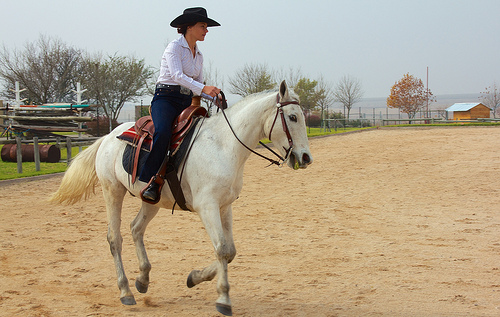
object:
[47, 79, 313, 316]
horse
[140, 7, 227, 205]
person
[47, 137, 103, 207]
tail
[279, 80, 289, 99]
ear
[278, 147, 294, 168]
bit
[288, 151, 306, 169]
mouth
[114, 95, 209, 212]
saddle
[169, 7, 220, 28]
hat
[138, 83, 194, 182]
jeans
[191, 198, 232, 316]
front leg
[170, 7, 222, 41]
head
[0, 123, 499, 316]
field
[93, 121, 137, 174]
back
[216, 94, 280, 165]
reins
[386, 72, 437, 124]
tree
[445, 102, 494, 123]
structure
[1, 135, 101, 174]
fence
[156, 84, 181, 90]
belt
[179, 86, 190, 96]
buckle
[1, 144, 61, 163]
cylinder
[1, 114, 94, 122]
poles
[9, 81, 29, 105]
support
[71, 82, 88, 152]
support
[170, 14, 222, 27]
brim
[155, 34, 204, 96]
shirt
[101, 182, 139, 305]
leg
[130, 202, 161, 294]
leg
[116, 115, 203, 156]
blanket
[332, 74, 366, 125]
tree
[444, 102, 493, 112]
roof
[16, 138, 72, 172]
section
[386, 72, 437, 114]
fall leaves